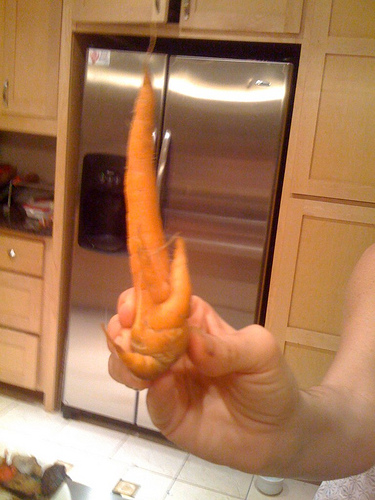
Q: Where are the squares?
A: Floor.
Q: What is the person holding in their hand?
A: Carrot.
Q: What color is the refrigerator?
A: Silver.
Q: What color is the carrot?
A: Orange.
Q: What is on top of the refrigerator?
A: Cabinet.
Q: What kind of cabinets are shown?
A: Wood.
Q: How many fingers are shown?
A: Four.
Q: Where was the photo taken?
A: The kitchen.